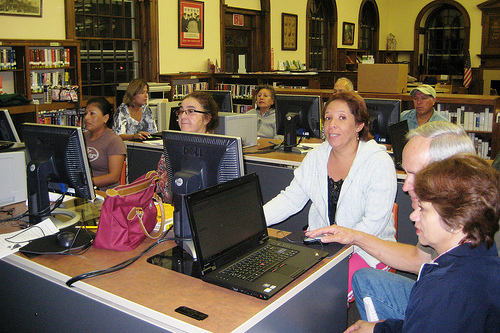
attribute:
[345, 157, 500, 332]
woman — sitting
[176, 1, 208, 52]
picture — framed, hanging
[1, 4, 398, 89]
wall — yellow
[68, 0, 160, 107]
window — large, closed, open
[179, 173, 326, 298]
laptop — black, off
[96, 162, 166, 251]
bag — pink, brown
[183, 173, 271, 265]
screen — off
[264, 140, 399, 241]
jacket — white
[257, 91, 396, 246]
woman — smiling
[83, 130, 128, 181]
shirt — brown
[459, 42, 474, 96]
flag — american